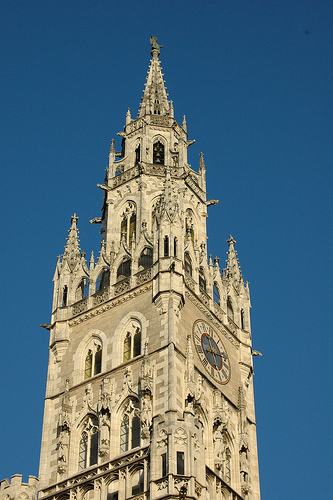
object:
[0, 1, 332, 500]
sky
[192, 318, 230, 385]
clock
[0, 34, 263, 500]
cathedral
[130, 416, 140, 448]
windows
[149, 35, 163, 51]
statue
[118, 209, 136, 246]
two windows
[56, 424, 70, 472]
carvings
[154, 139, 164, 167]
small window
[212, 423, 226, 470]
religious statue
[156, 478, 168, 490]
small scripture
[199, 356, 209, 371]
roman numerals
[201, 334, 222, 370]
center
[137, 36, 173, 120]
roof